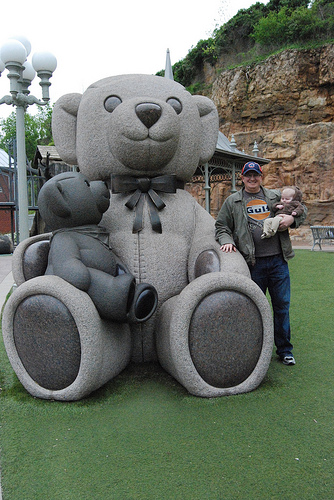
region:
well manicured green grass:
[40, 423, 204, 470]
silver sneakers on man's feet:
[281, 352, 298, 371]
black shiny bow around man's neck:
[114, 168, 190, 233]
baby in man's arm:
[267, 187, 313, 249]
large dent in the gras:
[162, 372, 290, 419]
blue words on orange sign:
[238, 196, 278, 226]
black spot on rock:
[280, 45, 319, 96]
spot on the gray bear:
[176, 241, 227, 297]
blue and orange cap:
[236, 157, 273, 180]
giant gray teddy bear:
[20, 61, 273, 369]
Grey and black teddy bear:
[34, 168, 161, 324]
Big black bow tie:
[109, 171, 178, 234]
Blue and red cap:
[239, 159, 262, 179]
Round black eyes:
[102, 93, 184, 112]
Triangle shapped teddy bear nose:
[134, 100, 163, 130]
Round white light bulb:
[30, 50, 57, 72]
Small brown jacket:
[269, 185, 305, 217]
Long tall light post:
[0, 30, 60, 246]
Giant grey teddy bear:
[1, 71, 271, 399]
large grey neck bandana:
[48, 224, 111, 248]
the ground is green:
[144, 411, 221, 491]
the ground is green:
[128, 391, 206, 476]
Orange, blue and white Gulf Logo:
[243, 197, 273, 222]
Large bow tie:
[105, 169, 189, 237]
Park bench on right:
[305, 217, 332, 248]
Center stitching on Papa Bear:
[127, 201, 149, 281]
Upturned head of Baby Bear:
[24, 165, 115, 230]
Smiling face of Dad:
[233, 157, 264, 192]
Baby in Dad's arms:
[256, 181, 306, 242]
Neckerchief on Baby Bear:
[49, 221, 115, 248]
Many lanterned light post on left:
[0, 30, 61, 238]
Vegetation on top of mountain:
[171, 0, 333, 90]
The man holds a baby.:
[190, 157, 322, 274]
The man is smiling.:
[234, 162, 268, 195]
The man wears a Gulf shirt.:
[236, 190, 272, 224]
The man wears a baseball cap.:
[231, 157, 269, 179]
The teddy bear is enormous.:
[0, 72, 285, 426]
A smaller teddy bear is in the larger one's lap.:
[23, 159, 172, 339]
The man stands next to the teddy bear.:
[187, 142, 325, 380]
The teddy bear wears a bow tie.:
[78, 162, 201, 246]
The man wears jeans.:
[233, 249, 307, 364]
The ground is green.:
[1, 349, 332, 498]